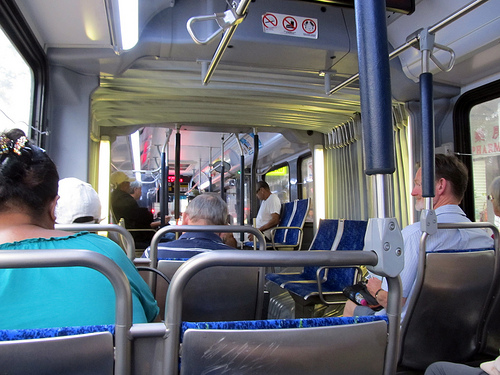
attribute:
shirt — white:
[257, 186, 289, 250]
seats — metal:
[0, 215, 496, 372]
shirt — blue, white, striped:
[152, 228, 246, 254]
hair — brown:
[0, 124, 68, 230]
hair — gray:
[180, 188, 238, 222]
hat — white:
[56, 174, 104, 228]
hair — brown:
[424, 148, 468, 203]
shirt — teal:
[0, 234, 162, 345]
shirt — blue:
[158, 223, 246, 263]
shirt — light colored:
[371, 200, 483, 293]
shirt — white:
[254, 189, 296, 237]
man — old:
[340, 146, 482, 354]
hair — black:
[427, 150, 465, 213]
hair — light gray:
[188, 190, 231, 229]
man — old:
[132, 192, 257, 258]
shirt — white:
[262, 214, 266, 222]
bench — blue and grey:
[165, 245, 395, 352]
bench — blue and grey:
[308, 212, 332, 243]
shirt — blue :
[2, 266, 108, 347]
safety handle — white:
[176, 50, 200, 52]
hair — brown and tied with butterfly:
[0, 125, 37, 165]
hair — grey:
[192, 195, 221, 215]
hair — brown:
[441, 152, 474, 193]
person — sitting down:
[385, 158, 495, 308]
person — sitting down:
[142, 178, 253, 268]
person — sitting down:
[28, 161, 139, 297]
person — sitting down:
[0, 129, 160, 328]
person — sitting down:
[96, 178, 193, 253]